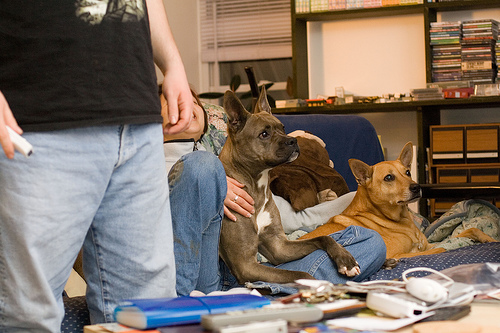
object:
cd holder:
[431, 123, 497, 153]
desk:
[424, 102, 496, 183]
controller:
[6, 125, 34, 157]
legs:
[417, 226, 498, 254]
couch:
[221, 112, 498, 289]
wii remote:
[364, 292, 429, 318]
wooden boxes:
[430, 125, 466, 159]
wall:
[350, 40, 440, 85]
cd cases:
[429, 20, 494, 85]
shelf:
[272, 94, 498, 115]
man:
[0, 1, 196, 333]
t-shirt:
[3, 0, 165, 135]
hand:
[222, 175, 257, 222]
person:
[158, 71, 388, 294]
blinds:
[199, 0, 293, 63]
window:
[200, 4, 296, 100]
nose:
[409, 183, 420, 193]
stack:
[429, 10, 458, 85]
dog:
[296, 139, 497, 268]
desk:
[253, 0, 498, 200]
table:
[83, 269, 500, 332]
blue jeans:
[2, 123, 179, 332]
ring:
[232, 195, 239, 203]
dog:
[268, 132, 349, 214]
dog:
[204, 84, 360, 282]